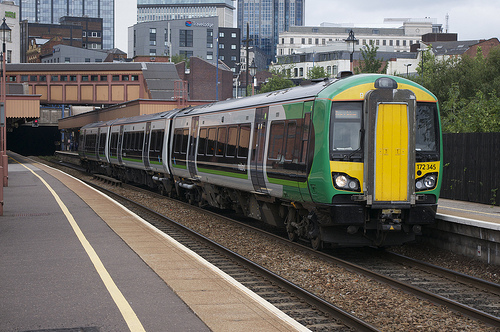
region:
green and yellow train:
[60, 108, 458, 229]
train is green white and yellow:
[78, 73, 442, 253]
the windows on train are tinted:
[80, 101, 314, 191]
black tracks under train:
[22, 149, 498, 330]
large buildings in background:
[0, 1, 499, 101]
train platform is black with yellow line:
[1, 153, 308, 330]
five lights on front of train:
[331, 77, 438, 202]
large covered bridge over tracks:
[0, 60, 216, 117]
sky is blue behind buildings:
[111, 0, 496, 51]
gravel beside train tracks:
[27, 150, 497, 330]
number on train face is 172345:
[414, 159, 439, 176]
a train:
[208, 82, 348, 156]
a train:
[264, 47, 387, 228]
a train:
[256, 132, 377, 312]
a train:
[291, 103, 353, 209]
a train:
[243, 77, 331, 256]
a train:
[264, 124, 289, 174]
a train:
[324, 130, 413, 296]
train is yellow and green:
[178, 158, 361, 239]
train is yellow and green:
[245, 128, 298, 249]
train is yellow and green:
[317, 200, 349, 257]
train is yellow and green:
[192, 90, 360, 322]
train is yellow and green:
[216, 40, 396, 275]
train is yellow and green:
[297, 46, 432, 296]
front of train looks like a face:
[315, 62, 449, 239]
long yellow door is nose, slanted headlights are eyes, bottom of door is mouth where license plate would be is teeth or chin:
[330, 80, 440, 240]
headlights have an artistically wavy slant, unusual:
[327, 163, 442, 200]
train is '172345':
[410, 158, 438, 176]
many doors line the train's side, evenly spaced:
[72, 98, 300, 205]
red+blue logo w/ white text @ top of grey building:
[179, 16, 217, 32]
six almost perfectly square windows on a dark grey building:
[214, 26, 241, 68]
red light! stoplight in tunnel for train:
[30, 116, 42, 127]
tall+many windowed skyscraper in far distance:
[232, 0, 305, 97]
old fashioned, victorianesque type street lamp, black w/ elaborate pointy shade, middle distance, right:
[338, 20, 363, 75]